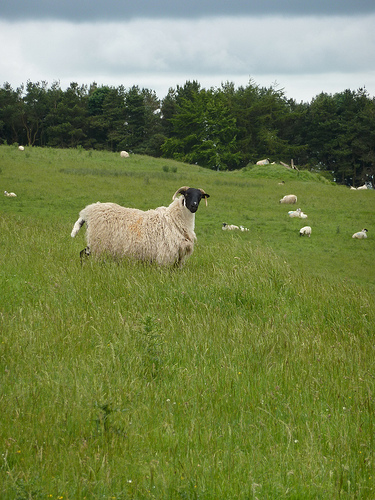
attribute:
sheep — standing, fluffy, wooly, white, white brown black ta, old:
[71, 183, 211, 264]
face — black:
[179, 188, 204, 214]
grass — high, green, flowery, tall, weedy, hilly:
[2, 143, 374, 498]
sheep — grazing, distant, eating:
[278, 191, 298, 205]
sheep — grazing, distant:
[285, 208, 308, 221]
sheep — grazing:
[295, 223, 313, 239]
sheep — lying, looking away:
[350, 225, 370, 239]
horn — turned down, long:
[171, 184, 185, 202]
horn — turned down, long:
[199, 187, 209, 210]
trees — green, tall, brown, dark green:
[1, 77, 374, 189]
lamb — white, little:
[2, 189, 21, 198]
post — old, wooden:
[290, 158, 296, 172]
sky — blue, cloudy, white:
[0, 0, 375, 109]